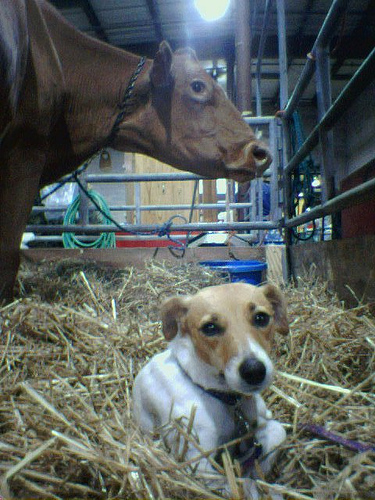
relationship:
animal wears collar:
[131, 278, 290, 497] [178, 353, 247, 400]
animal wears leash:
[131, 278, 290, 497] [221, 400, 263, 496]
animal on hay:
[131, 278, 290, 497] [0, 256, 375, 499]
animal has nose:
[131, 278, 290, 497] [240, 359, 266, 383]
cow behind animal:
[0, 0, 273, 306] [131, 278, 290, 497]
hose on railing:
[60, 188, 118, 252] [78, 205, 172, 262]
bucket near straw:
[185, 253, 278, 303] [22, 253, 369, 332]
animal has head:
[131, 278, 290, 497] [157, 280, 285, 390]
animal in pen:
[131, 279, 284, 498] [3, 4, 363, 494]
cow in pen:
[0, 0, 276, 306] [3, 4, 363, 494]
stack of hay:
[12, 261, 374, 498] [2, 278, 374, 498]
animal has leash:
[131, 278, 290, 497] [296, 421, 371, 465]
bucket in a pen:
[194, 260, 267, 286] [36, 242, 360, 296]